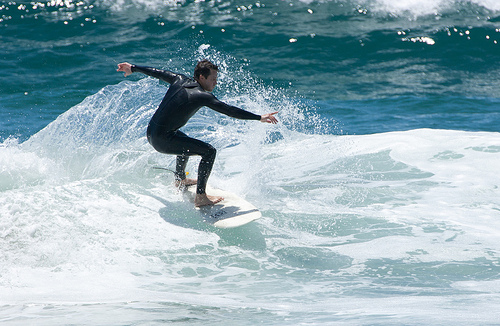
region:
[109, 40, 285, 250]
a surfer in the ocean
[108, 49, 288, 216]
surfer wears a black wetsuit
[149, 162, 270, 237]
a white surfboard in the ocean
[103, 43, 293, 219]
surfer is crouched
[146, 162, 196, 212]
rope tied in foot of surfer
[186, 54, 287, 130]
right hand is extended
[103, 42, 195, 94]
left hand is extended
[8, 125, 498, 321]
foamy water around surfer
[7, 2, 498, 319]
water in the ocean is choppy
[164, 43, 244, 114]
man has black hair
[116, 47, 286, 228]
a man on a surf board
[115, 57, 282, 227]
a man surfing a wave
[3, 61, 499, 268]
a beautiful white wave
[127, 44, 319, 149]
ocean spray from a wave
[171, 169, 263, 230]
a white surf board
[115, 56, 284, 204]
a man in a black wet suite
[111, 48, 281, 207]
a bare footed man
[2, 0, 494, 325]
the blue green and white ocean water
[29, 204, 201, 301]
a patch of sea foam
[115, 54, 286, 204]
a surfer dressed in all black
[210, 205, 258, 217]
A surf board in the water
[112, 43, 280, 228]
A man riding a wave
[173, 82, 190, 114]
A black wet suit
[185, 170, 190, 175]
A yellow spot on the surfing board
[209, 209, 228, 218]
Black writing on the surf board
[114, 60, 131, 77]
An exposed left hand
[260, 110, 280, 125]
The outstretched fingers of the hand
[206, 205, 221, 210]
The surfer's shadow on the board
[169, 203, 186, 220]
The surfer's shadow on the wave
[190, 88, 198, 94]
Light reflecting on the wet suit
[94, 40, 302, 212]
person surfing in ocean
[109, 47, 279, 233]
man wearing a black wet suit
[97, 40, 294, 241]
man with arms out to balance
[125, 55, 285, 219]
man on a white surfboard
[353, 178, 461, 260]
whie foam from crashing waves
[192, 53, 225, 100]
man with short brown hair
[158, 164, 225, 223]
man on surfboard with barefeet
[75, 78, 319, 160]
ocean spray caused by surfing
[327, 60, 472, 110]
clear blue ocean water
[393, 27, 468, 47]
light reflecting on water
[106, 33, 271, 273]
the man is surfing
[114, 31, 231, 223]
the man is wearing a wet suit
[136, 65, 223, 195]
the wet suit is black